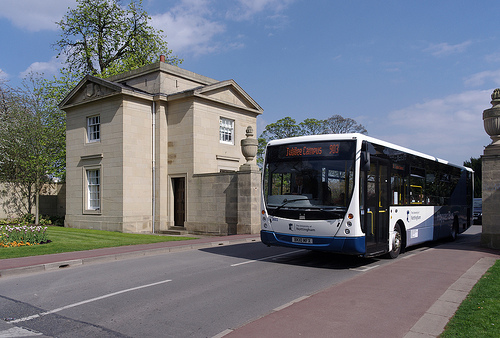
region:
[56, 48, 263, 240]
beige two story building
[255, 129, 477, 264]
white and blue large bus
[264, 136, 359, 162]
black digital sign with orange letters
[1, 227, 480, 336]
black asphalt road with white painted lines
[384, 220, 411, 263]
Black tire on a bus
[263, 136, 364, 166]
Reader sign on a bus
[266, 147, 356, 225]
Window on a bus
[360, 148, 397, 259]
Door on a bus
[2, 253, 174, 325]
White line on a road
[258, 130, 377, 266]
Front of a blue and white bus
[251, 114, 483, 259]
Blue and white bus on a road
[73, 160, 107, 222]
Window on a building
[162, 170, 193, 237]
Door on a building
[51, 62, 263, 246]
Gray building next to a road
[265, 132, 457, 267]
blue and white bus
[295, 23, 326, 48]
white clouds in blue sky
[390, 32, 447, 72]
white clouds in blue sky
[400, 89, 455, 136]
white clouds in blue sky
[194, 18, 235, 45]
white clouds in blue sky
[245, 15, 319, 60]
white clouds in blue sky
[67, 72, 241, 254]
tan house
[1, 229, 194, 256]
A well kept lawn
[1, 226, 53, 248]
A maintained flower bed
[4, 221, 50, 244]
Long stemmed purple flowers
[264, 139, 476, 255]
A blue and white bus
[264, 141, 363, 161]
An electronic sign displaying a destination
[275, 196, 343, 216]
one large windshield wiper blade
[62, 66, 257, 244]
A large stone gate house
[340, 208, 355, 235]
A set of indicator lights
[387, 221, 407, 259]
A large radial tire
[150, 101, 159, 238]
A gutter for rain water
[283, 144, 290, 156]
red letter on bus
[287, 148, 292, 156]
red letter on bus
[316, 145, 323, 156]
red letter on bus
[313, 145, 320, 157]
red letter on bus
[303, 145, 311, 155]
red letter on bus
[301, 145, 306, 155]
red letter on bus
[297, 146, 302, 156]
red letter on bus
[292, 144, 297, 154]
red letter on bus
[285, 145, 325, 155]
red letters on bus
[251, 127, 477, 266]
a bus on the road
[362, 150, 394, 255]
a door of the bus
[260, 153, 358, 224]
a windshield of the bus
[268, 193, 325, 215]
a wiper of the bus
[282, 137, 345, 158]
lights that say where the bus is going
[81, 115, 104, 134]
window on the building facing the camera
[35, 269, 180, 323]
white line marking on the road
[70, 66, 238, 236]
building beside the bus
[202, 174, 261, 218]
brick wall beside the building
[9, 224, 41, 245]
flowers in the landscape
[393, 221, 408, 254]
front tire of the bus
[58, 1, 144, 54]
tree above the building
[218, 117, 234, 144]
Window of a building